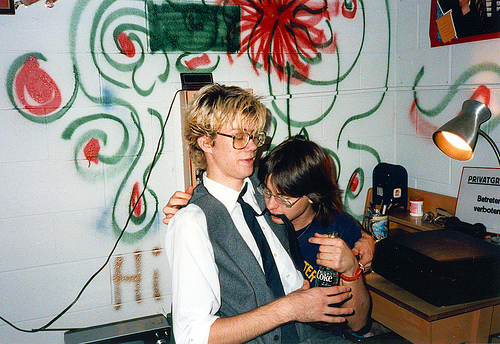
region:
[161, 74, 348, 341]
Man wearing a gray vest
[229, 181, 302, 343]
Tie on man's neck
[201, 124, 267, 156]
Eyeglasses on man's face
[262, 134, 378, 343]
Woman wearing a blue shirt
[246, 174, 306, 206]
Eyeglasses on woman's face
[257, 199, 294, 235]
Tie in woman's mouth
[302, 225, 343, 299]
Coke bottle in woman's hand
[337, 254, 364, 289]
Watch on woman's wrist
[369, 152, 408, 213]
Tiny mailbox on desk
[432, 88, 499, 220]
Lamp hanging over desk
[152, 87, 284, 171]
man hsa blonde hair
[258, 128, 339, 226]
man has brown hair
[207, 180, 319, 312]
man has white shirt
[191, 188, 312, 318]
man has grey vest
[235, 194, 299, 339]
man has blue tie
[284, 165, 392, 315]
man has blue shirt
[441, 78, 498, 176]
silver lamp on table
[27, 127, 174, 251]
wall is white brick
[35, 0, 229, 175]
green and red paint on wall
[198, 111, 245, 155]
man has black glasses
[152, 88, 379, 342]
two men being silly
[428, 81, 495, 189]
illuminated lamp on table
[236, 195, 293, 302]
tie on a man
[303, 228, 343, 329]
bottle of liquor in hands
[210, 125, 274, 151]
glasses on a man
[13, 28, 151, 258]
graffiti on a wall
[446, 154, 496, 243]
sign on a table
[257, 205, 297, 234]
tie in man's mouth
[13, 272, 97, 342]
black electrical wire by wall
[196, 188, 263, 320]
grey vest on a man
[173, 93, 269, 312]
this is a man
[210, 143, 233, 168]
the man is light skinned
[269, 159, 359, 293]
this is a lady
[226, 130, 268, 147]
this is a spectacle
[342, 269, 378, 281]
this is a watch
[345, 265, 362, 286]
the watch is red in color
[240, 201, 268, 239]
this is a neck tie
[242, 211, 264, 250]
the tie is black in color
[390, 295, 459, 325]
this is a table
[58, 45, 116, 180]
this is the wall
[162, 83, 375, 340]
the two men hugging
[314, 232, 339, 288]
the coke bottle in the man's hand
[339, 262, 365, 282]
the watch on the man's wrist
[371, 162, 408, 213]
the small container shaped like a post office mailbox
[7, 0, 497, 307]
the graffiti on the wall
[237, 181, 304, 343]
the long tie around the man's neck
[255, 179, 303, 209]
the glasses on the man's face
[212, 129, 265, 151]
the glasses on the man's face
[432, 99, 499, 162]
the desk lamp turned on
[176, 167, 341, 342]
the gray vest on the man